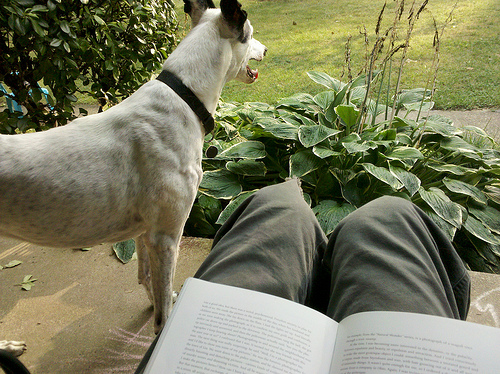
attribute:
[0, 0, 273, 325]
dog — a, white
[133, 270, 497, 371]
book — open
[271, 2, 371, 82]
field — large, grassy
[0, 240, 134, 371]
porch — concrete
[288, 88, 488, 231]
plant — leafy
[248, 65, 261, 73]
teeth — canine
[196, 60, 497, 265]
bush — green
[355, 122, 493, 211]
flowers — dead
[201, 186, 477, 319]
pants — off green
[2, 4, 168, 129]
bush — green, taller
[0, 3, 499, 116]
lawn — green, brown, the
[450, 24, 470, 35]
brown — slightly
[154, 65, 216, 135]
collar — black, dog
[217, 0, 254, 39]
ear — dog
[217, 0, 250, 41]
ear — brown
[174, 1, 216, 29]
ear — brown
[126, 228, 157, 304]
leg — 2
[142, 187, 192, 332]
leg — 2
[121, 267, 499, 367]
book — an, open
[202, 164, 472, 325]
lap — person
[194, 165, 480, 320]
person — a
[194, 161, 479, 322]
pants — gray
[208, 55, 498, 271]
plants — green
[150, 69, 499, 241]
ground — the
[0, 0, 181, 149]
shrubbery — green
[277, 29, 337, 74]
shadow — a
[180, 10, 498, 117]
grass — the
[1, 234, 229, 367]
ground — the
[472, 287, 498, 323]
mark — a, chalk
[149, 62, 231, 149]
collar — a, black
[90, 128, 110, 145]
white — mostly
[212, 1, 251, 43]
ear — brown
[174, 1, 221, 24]
ear — brown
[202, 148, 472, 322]
pants — green 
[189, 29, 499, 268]
plant — leafy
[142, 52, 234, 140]
collar — black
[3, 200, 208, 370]
concrete — tan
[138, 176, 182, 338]
leg — white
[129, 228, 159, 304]
leg — white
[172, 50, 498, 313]
plant — large, green 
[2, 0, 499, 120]
grass — low cut, green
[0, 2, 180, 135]
bush — large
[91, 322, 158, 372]
drawings — chalk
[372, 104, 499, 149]
sidewalk — concrete